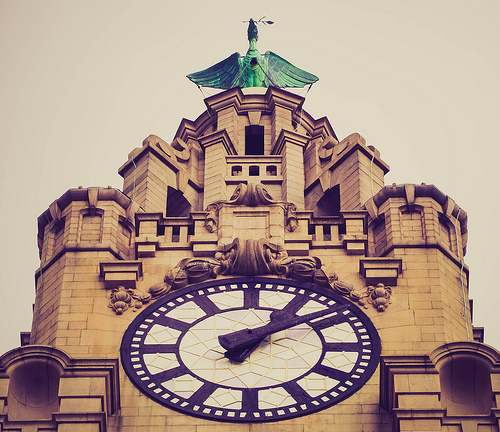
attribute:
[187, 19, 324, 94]
statue — green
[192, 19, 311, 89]
statue — green, on top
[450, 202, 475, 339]
pipe — steel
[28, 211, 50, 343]
pipe — steel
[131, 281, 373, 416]
clock face — white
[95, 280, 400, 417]
clock — white, black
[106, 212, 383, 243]
windows — closed arched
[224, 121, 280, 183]
windows — open arched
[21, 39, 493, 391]
building — old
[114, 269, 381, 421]
clock — large, black, white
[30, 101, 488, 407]
clocktower — clock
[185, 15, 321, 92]
statue — green, winged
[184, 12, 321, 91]
bird — green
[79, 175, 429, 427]
building — stone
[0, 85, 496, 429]
tower — tan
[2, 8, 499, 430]
building — decorated